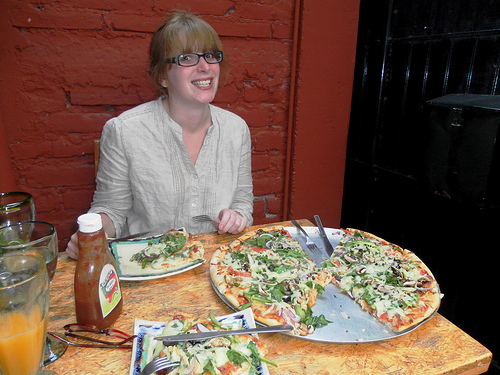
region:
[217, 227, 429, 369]
the pizza is sliced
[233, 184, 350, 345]
the pizza is sliced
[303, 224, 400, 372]
the pizza is sliced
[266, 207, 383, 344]
the pizza is sliced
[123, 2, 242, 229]
this is a lady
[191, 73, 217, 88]
the mouth is open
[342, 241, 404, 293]
this is a pizza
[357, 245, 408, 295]
the pizza is big in size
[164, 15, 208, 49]
the hair is pale brown in color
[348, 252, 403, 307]
the pizza is spicy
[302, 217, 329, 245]
this is a fork and a knife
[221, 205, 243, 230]
these are the fingers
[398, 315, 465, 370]
the table is wooden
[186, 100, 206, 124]
the lady is light skinned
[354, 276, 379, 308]
A pizza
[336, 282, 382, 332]
A pizza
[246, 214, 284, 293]
A pizza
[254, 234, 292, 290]
A pizza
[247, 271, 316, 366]
A pizza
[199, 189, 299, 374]
A pizza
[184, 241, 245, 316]
A pizza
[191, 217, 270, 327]
A pizza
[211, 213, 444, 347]
Partly eaten pizza with fresh herbs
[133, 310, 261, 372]
Plate with pizza, knife, and fork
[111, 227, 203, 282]
Plate with partially eaten pizza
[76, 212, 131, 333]
Squeeze bottle of sauce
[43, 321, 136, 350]
Red pair of eye glasses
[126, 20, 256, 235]
Lady smiling and holding fork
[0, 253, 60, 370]
Glass of orange beverage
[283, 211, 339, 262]
Fork and knife on pizza tray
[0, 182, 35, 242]
Part of drinking glass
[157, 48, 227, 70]
Dark colored eyeglasses on woman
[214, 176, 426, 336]
pizza on a tray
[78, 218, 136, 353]
bottle next to pizza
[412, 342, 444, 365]
table beneath the pizza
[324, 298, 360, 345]
missing piece of pizza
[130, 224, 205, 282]
half eaten pizza on plate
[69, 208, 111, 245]
white top on bottle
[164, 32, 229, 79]
glasses on woman's face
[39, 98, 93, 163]
red wall behind lady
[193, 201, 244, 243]
woman holding a fork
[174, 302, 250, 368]
full plate of food